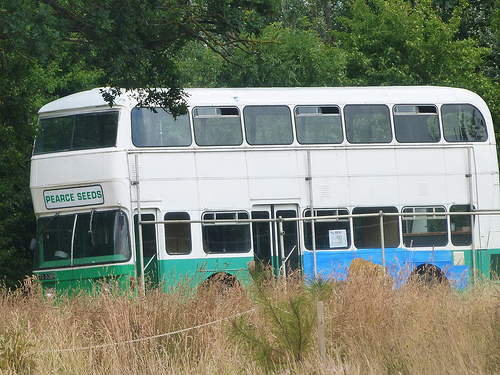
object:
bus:
[30, 85, 500, 307]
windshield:
[33, 208, 131, 270]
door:
[133, 208, 159, 301]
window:
[164, 212, 192, 255]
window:
[201, 209, 252, 254]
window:
[303, 208, 351, 251]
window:
[352, 206, 399, 249]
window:
[401, 205, 449, 248]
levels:
[29, 86, 498, 219]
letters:
[43, 184, 104, 210]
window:
[191, 105, 243, 146]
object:
[329, 229, 348, 248]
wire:
[15, 303, 272, 358]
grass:
[0, 259, 500, 375]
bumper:
[32, 261, 138, 304]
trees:
[0, 1, 500, 120]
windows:
[341, 103, 391, 145]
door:
[251, 203, 303, 294]